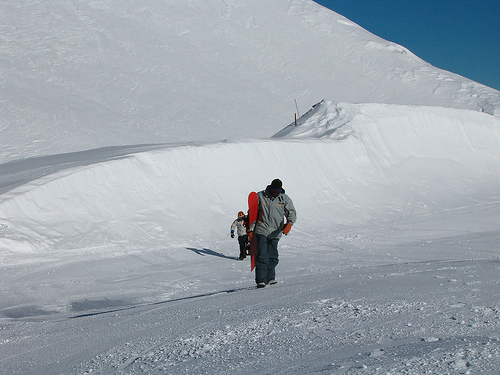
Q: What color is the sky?
A: Blue.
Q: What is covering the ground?
A: Snow.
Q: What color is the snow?
A: White.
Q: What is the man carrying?
A: A snowboard.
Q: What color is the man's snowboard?
A: Orange.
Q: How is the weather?
A: Clear.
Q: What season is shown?
A: Winter.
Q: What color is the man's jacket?
A: Grey.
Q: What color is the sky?
A: Blue.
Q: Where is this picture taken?
A: A ski slope.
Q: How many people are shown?
A: 2.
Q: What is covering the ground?
A: Snow.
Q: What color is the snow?
A: White.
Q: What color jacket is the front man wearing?
A: Gray.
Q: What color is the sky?
A: Blue.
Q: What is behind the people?
A: Hill.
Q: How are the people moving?
A: Walking.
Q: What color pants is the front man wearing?
A: Black.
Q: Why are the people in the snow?
A: To snowboard.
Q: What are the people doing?
A: Walking.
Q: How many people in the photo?
A: Two.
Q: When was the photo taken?
A: Day time.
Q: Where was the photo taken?
A: Mountain.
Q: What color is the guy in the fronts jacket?
A: Gray.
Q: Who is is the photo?
A: Men.